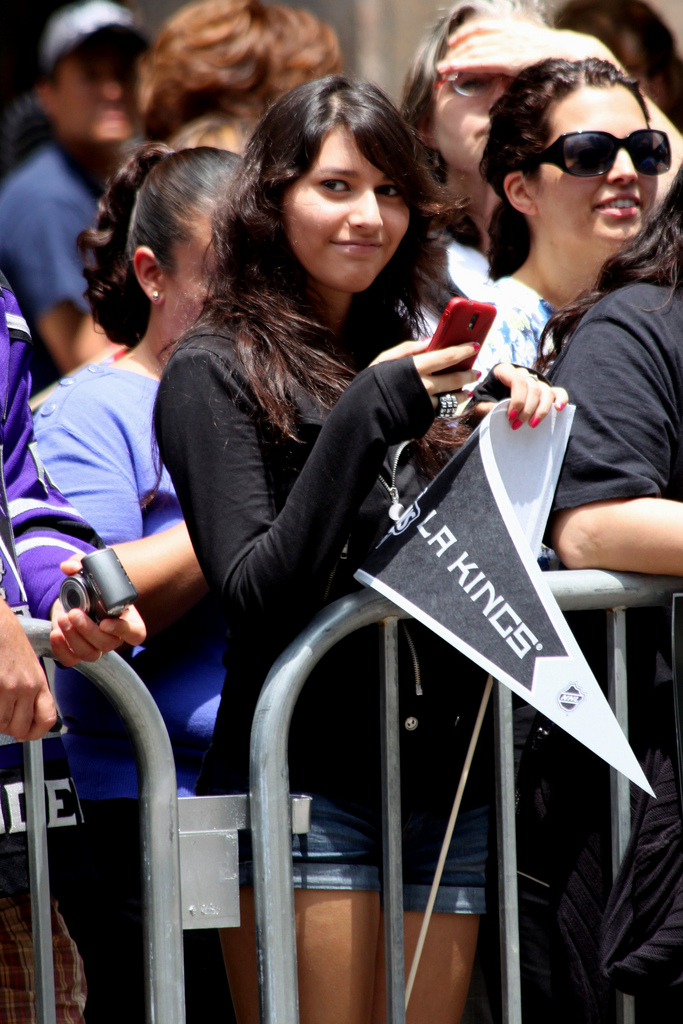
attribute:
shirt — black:
[147, 286, 524, 817]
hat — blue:
[3, 2, 159, 82]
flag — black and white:
[336, 382, 665, 803]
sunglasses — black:
[469, 119, 678, 194]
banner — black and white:
[331, 373, 666, 835]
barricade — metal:
[239, 565, 679, 1022]